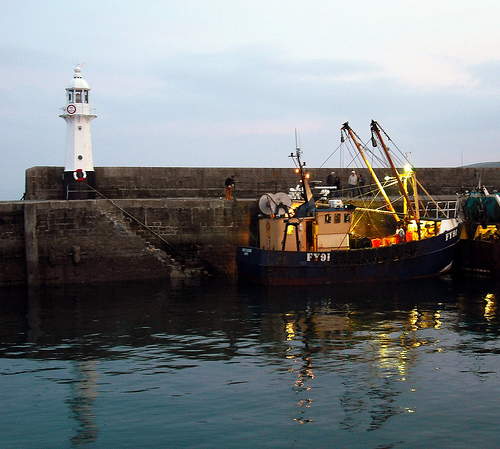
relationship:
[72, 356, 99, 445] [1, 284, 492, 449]
refelction on top of water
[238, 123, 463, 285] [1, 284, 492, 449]
boat on top of water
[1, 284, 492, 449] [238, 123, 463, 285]
water underneath boat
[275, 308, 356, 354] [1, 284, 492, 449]
reflection on water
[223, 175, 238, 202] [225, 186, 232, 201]
man in pants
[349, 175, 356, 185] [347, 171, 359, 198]
shirt on man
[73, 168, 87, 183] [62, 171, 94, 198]
life saver on base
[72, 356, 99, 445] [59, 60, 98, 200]
refelction of lighthouse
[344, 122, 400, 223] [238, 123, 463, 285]
crane on top of boat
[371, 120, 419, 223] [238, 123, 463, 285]
crane on top of boat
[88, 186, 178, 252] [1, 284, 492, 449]
rail near water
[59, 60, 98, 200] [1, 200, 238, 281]
lighthouse on pier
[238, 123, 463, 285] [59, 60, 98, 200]
boat nearby white lighthouse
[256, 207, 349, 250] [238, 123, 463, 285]
room on deck of boat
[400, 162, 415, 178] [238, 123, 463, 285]
light on top of boat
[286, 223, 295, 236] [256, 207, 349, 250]
sign on side of room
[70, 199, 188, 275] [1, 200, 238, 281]
stairway on pier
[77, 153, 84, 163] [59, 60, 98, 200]
window on lighthouse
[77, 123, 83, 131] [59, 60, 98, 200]
window on lighthouse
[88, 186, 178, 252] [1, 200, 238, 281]
rail on side of pier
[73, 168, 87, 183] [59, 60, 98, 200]
life saver on lighthouse